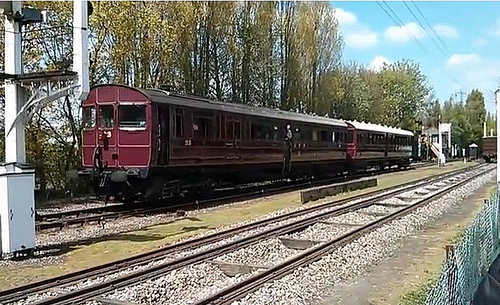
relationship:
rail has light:
[0, 161, 499, 303] [70, 0, 99, 28]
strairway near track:
[424, 137, 449, 163] [5, 164, 499, 303]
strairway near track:
[424, 137, 449, 163] [31, 194, 125, 229]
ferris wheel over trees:
[447, 84, 473, 114] [432, 98, 494, 155]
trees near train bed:
[31, 0, 488, 158] [12, 113, 498, 298]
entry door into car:
[155, 103, 170, 167] [76, 80, 346, 203]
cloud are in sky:
[367, 55, 392, 71] [334, 11, 459, 75]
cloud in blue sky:
[446, 53, 500, 84] [424, 3, 499, 22]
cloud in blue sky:
[429, 23, 457, 38] [424, 3, 499, 22]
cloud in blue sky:
[383, 22, 460, 44] [424, 3, 499, 22]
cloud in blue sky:
[322, 7, 357, 26] [424, 3, 499, 22]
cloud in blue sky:
[343, 29, 378, 47] [424, 3, 499, 22]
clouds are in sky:
[318, 7, 500, 120] [332, 10, 482, 75]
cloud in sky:
[446, 53, 500, 84] [0, 0, 497, 149]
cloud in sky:
[471, 27, 498, 53] [0, 0, 497, 149]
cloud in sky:
[383, 19, 460, 44] [0, 0, 497, 149]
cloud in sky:
[322, 7, 357, 26] [0, 0, 497, 149]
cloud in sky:
[367, 55, 392, 71] [0, 0, 497, 149]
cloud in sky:
[328, 7, 365, 26] [327, 4, 495, 77]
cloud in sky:
[343, 29, 378, 47] [327, 4, 495, 77]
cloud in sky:
[380, 17, 461, 44] [327, 4, 495, 77]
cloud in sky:
[367, 55, 392, 71] [327, 4, 495, 77]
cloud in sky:
[447, 50, 499, 92] [327, 4, 495, 77]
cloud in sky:
[385, 21, 425, 42] [0, 0, 497, 149]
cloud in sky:
[429, 23, 457, 38] [0, 0, 497, 149]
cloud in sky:
[343, 29, 378, 47] [0, 0, 497, 149]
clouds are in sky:
[318, 7, 500, 120] [337, 0, 497, 80]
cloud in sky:
[323, 5, 375, 51] [0, 0, 497, 132]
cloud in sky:
[367, 55, 392, 71] [0, 0, 497, 132]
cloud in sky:
[385, 20, 457, 43] [0, 0, 497, 132]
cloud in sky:
[474, 35, 490, 47] [0, 0, 497, 132]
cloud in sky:
[446, 53, 500, 84] [0, 0, 497, 132]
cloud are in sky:
[429, 23, 457, 38] [339, 3, 488, 62]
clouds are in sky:
[318, 7, 500, 120] [419, 6, 477, 65]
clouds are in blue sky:
[318, 7, 500, 120] [328, 1, 500, 116]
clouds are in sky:
[4, 5, 499, 120] [0, 0, 497, 149]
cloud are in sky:
[322, 7, 357, 26] [5, 0, 494, 110]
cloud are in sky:
[343, 29, 378, 47] [5, 0, 494, 110]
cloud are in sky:
[385, 21, 425, 42] [5, 0, 494, 110]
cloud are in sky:
[429, 23, 457, 38] [5, 0, 494, 110]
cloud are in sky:
[446, 53, 500, 84] [5, 0, 494, 110]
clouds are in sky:
[318, 7, 500, 120] [0, 0, 497, 132]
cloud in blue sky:
[446, 53, 500, 84] [328, 2, 498, 116]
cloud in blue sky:
[429, 23, 457, 38] [328, 2, 498, 116]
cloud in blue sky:
[385, 21, 425, 42] [328, 2, 498, 116]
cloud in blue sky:
[367, 55, 392, 71] [328, 2, 498, 116]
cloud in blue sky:
[330, 6, 378, 51] [328, 2, 498, 116]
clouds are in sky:
[366, 13, 493, 80] [364, 9, 494, 62]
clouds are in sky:
[318, 7, 500, 120] [317, 5, 495, 102]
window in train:
[80, 95, 114, 131] [81, 59, 428, 197]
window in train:
[77, 102, 113, 129] [72, 72, 422, 174]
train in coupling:
[67, 74, 397, 194] [78, 140, 149, 187]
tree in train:
[462, 86, 487, 138] [73, 83, 413, 203]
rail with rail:
[0, 161, 499, 303] [287, 245, 317, 267]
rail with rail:
[0, 161, 499, 303] [197, 242, 245, 254]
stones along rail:
[288, 270, 333, 291] [287, 245, 317, 267]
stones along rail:
[327, 250, 367, 272] [287, 245, 317, 267]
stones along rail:
[376, 227, 406, 248] [287, 245, 317, 267]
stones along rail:
[184, 263, 214, 281] [197, 242, 245, 254]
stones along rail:
[254, 239, 285, 253] [197, 242, 245, 254]